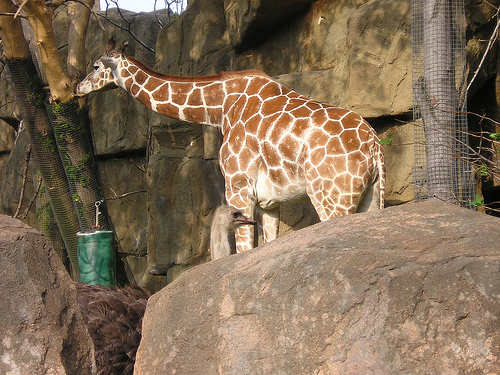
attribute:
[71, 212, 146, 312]
trashcan — green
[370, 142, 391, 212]
tail — brown 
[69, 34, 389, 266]
giraffe — brown and white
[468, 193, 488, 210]
leaf — green 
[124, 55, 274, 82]
mane — brown 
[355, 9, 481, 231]
tree — long 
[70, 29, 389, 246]
giraffe — tall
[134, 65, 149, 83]
spot — brown , white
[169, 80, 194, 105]
spot — brown , white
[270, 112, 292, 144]
spot — brown , white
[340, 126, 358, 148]
spot — brown , white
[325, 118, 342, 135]
spot — brown , white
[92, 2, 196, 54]
tree — bare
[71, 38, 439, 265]
giraffe — eating 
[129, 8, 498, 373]
rocks — brown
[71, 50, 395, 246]
giraffe — brown , white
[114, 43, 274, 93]
mane — short 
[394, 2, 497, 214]
fence — grey , mesh 